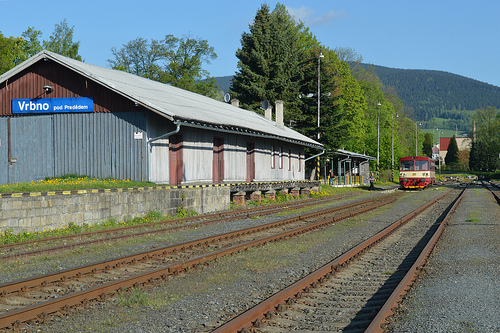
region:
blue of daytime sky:
[0, 1, 497, 86]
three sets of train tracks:
[1, 177, 472, 331]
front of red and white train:
[397, 156, 434, 189]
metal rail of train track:
[366, 186, 468, 331]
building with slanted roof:
[0, 50, 321, 183]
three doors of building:
[170, 134, 255, 184]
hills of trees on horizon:
[200, 58, 498, 137]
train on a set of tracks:
[394, 152, 435, 191]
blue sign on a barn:
[8, 94, 96, 115]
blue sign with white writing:
[9, 95, 98, 113]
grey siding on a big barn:
[3, 113, 153, 186]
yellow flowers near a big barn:
[6, 174, 132, 185]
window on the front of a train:
[399, 158, 429, 171]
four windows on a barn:
[267, 142, 305, 171]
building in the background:
[428, 113, 479, 169]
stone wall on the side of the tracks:
[0, 185, 233, 229]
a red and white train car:
[394, 152, 436, 192]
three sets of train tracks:
[138, 217, 416, 307]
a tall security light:
[313, 46, 325, 140]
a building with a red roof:
[438, 132, 457, 162]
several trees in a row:
[317, 45, 424, 148]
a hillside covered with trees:
[395, 63, 491, 102]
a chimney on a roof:
[273, 95, 290, 126]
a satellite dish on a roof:
[257, 97, 275, 115]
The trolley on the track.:
[400, 154, 436, 189]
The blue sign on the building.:
[9, 97, 96, 115]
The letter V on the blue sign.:
[17, 99, 24, 111]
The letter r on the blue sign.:
[24, 104, 29, 111]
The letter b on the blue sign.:
[30, 99, 36, 109]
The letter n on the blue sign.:
[35, 100, 41, 111]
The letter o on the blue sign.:
[41, 102, 48, 113]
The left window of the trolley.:
[403, 159, 414, 171]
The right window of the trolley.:
[415, 157, 427, 170]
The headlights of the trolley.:
[400, 172, 427, 177]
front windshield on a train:
[395, 159, 433, 173]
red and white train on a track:
[398, 155, 433, 187]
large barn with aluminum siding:
[2, 47, 332, 200]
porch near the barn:
[219, 175, 320, 203]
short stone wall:
[3, 186, 235, 237]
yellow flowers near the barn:
[20, 171, 130, 190]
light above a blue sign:
[39, 81, 55, 93]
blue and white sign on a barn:
[10, 96, 97, 113]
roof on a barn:
[45, 47, 325, 144]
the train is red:
[380, 143, 442, 207]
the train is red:
[387, 136, 432, 196]